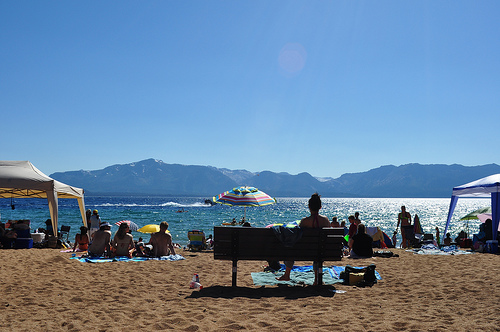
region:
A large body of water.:
[1, 189, 497, 242]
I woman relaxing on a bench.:
[276, 190, 333, 289]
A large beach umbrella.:
[214, 180, 276, 225]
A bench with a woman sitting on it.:
[210, 225, 344, 292]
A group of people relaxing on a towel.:
[82, 220, 186, 262]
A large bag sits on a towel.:
[338, 262, 378, 285]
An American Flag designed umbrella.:
[112, 215, 142, 231]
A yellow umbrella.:
[137, 219, 169, 235]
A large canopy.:
[1, 157, 91, 245]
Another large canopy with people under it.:
[438, 170, 499, 249]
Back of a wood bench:
[210, 222, 344, 287]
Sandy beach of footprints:
[13, 268, 186, 329]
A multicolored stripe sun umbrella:
[215, 185, 275, 217]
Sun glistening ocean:
[343, 196, 397, 211]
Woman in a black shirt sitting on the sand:
[348, 221, 375, 263]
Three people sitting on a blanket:
[87, 221, 174, 259]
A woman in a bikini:
[396, 201, 414, 247]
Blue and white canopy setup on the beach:
[440, 171, 499, 256]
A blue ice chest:
[13, 233, 33, 250]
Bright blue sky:
[276, 78, 498, 154]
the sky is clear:
[86, 74, 338, 257]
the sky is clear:
[161, 50, 282, 212]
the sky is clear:
[141, 96, 248, 190]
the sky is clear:
[49, 10, 193, 142]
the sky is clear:
[90, 51, 242, 227]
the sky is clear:
[92, 46, 202, 153]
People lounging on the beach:
[61, 206, 181, 273]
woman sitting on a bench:
[197, 200, 388, 308]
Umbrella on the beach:
[200, 160, 303, 279]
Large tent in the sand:
[3, 152, 87, 244]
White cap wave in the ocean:
[104, 192, 216, 213]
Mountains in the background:
[62, 127, 476, 209]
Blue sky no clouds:
[170, 5, 442, 202]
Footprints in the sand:
[17, 274, 171, 330]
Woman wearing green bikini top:
[384, 184, 431, 250]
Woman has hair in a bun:
[290, 181, 339, 228]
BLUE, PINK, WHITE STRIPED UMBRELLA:
[206, 183, 279, 209]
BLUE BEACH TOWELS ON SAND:
[66, 247, 188, 267]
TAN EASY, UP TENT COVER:
[1, 155, 98, 254]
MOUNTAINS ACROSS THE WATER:
[99, 152, 204, 200]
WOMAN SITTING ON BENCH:
[213, 186, 350, 299]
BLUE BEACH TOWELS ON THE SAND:
[248, 262, 394, 297]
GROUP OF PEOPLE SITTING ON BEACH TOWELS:
[68, 220, 184, 267]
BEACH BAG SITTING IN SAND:
[339, 261, 391, 293]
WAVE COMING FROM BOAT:
[88, 196, 217, 211]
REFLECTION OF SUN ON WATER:
[324, 189, 491, 209]